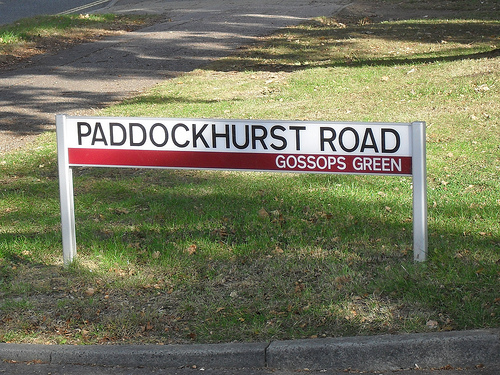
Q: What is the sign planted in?
A: Grass.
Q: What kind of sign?
A: Street sign.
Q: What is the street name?
A: Paddockhurst road.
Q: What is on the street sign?
A: Red bar.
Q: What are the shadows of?
A: Trees.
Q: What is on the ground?
A: Grass.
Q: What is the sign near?
A: Curb.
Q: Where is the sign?
A: Grass.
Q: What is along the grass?
A: Curb.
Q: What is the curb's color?
A: Grey.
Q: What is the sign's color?
A: White.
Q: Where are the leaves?
A: On the grass.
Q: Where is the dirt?
A: Beside the road.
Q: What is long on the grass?
A: The sign.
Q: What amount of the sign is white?
A: Half.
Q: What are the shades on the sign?
A: White and red.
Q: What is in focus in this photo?
A: The sign on the grass.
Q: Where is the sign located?
A: Next to a street.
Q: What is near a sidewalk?
A: The sign.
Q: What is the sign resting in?
A: Grass.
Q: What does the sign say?
A: Paddockhurst road.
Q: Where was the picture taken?
A: The street.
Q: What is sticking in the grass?
A: A sign.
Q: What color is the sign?
A: White and red.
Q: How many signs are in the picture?
A: One.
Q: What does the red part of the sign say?
A: Gossops Green.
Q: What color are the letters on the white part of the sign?
A: Black.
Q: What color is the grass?
A: Green.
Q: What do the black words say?
A: Paddockhurst Road.